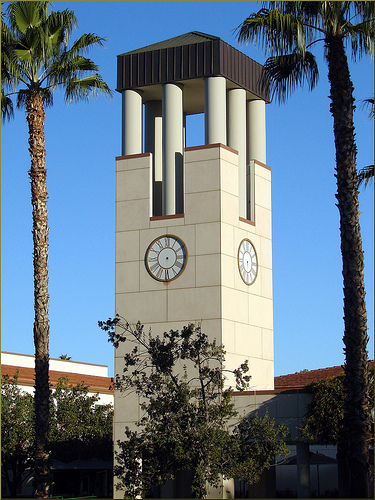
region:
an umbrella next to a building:
[280, 448, 338, 474]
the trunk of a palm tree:
[20, 91, 59, 496]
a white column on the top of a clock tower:
[157, 80, 183, 211]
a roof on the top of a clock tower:
[117, 29, 272, 100]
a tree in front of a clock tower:
[115, 366, 264, 497]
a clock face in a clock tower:
[145, 232, 190, 282]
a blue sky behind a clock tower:
[1, 0, 373, 375]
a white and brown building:
[1, 349, 121, 437]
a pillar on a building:
[292, 442, 313, 498]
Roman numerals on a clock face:
[147, 235, 185, 278]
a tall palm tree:
[0, 4, 113, 490]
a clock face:
[142, 233, 191, 282]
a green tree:
[102, 312, 292, 497]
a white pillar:
[157, 73, 192, 225]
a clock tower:
[108, 30, 283, 495]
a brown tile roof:
[1, 347, 112, 412]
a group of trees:
[1, 367, 106, 495]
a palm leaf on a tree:
[260, 40, 320, 101]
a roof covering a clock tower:
[108, 17, 273, 107]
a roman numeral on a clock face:
[161, 232, 172, 248]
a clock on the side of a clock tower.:
[141, 226, 189, 288]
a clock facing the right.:
[237, 237, 260, 287]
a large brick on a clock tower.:
[164, 286, 221, 321]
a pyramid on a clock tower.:
[117, 30, 273, 116]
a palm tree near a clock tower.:
[0, 3, 114, 494]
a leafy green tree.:
[90, 302, 274, 498]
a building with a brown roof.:
[0, 351, 116, 416]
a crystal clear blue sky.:
[0, 0, 373, 379]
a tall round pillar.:
[159, 78, 186, 218]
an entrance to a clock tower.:
[135, 427, 205, 496]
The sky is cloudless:
[276, 224, 353, 359]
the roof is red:
[297, 368, 340, 382]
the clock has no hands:
[128, 233, 200, 286]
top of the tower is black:
[136, 35, 267, 83]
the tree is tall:
[282, 9, 372, 491]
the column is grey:
[162, 106, 185, 212]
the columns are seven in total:
[126, 107, 269, 147]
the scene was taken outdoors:
[1, 162, 371, 494]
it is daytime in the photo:
[6, 44, 374, 469]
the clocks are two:
[133, 231, 278, 300]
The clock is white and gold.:
[146, 237, 199, 297]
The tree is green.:
[105, 315, 261, 484]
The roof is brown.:
[284, 355, 333, 395]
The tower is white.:
[125, 286, 261, 362]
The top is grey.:
[124, 26, 269, 115]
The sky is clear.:
[279, 127, 332, 361]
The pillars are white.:
[101, 73, 267, 207]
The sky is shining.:
[12, 135, 359, 438]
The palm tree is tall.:
[0, 8, 102, 145]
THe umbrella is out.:
[279, 449, 354, 477]